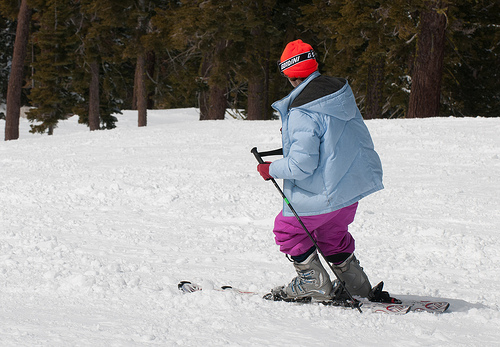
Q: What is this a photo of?
A: A skier.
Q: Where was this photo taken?
A: A ski park.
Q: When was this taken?
A: During the wintertime.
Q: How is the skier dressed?
A: He has on a ski coat, boots, jacket and hat.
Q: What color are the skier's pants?
A: Hot pink.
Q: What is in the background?
A: Evergreen trees.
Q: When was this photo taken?
A: Daytime.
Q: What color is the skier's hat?
A: Fluorescent red.